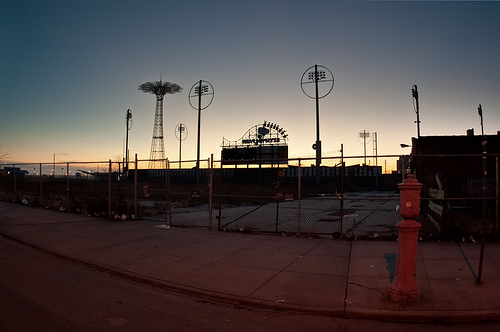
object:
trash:
[428, 172, 500, 232]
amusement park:
[0, 0, 500, 332]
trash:
[1, 195, 137, 221]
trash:
[218, 228, 500, 244]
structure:
[300, 64, 334, 185]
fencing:
[0, 153, 500, 240]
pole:
[477, 104, 483, 136]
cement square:
[0, 191, 500, 332]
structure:
[388, 173, 423, 303]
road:
[0, 200, 500, 332]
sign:
[242, 134, 280, 146]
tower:
[137, 72, 183, 169]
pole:
[312, 64, 321, 183]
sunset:
[128, 111, 385, 173]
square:
[0, 0, 500, 332]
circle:
[187, 80, 216, 111]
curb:
[1, 201, 500, 331]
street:
[0, 0, 500, 332]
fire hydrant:
[389, 173, 423, 303]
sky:
[0, 0, 500, 179]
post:
[297, 160, 301, 238]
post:
[208, 153, 214, 231]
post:
[133, 153, 138, 221]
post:
[107, 159, 112, 219]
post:
[65, 163, 69, 212]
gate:
[167, 153, 213, 231]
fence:
[0, 153, 499, 240]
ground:
[0, 189, 500, 332]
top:
[137, 72, 184, 95]